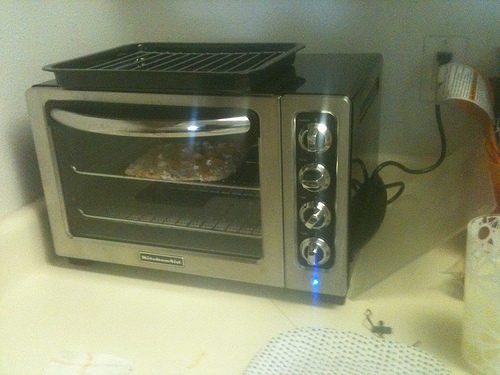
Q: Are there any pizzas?
A: Yes, there is a pizza.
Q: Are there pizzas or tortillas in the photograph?
A: Yes, there is a pizza.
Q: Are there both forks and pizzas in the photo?
A: No, there is a pizza but no forks.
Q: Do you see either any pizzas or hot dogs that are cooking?
A: Yes, the pizza is cooking.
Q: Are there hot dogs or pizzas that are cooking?
A: Yes, the pizza is cooking.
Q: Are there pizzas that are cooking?
A: Yes, there is a pizza that is cooking.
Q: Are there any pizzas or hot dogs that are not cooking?
A: No, there is a pizza but it is cooking.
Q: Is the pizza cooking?
A: Yes, the pizza is cooking.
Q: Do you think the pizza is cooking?
A: Yes, the pizza is cooking.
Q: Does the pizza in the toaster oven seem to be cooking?
A: Yes, the pizza is cooking.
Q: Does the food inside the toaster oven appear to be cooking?
A: Yes, the pizza is cooking.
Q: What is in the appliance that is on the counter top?
A: The pizza is in the toaster oven.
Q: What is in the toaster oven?
A: The pizza is in the toaster oven.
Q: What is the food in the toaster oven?
A: The food is a pizza.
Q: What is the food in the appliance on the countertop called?
A: The food is a pizza.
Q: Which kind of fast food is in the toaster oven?
A: The food is a pizza.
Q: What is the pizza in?
A: The pizza is in the toaster oven.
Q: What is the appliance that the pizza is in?
A: The appliance is a toaster oven.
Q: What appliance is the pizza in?
A: The pizza is in the toaster oven.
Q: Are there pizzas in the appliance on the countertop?
A: Yes, there is a pizza in the toaster oven.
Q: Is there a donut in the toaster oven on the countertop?
A: No, there is a pizza in the toaster oven.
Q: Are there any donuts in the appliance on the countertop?
A: No, there is a pizza in the toaster oven.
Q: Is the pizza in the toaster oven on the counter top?
A: Yes, the pizza is in the toaster oven.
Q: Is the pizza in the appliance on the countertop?
A: Yes, the pizza is in the toaster oven.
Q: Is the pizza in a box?
A: No, the pizza is in the toaster oven.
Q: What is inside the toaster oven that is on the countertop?
A: The pizza is inside the toaster oven.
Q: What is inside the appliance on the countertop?
A: The pizza is inside the toaster oven.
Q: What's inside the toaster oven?
A: The pizza is inside the toaster oven.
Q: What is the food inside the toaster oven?
A: The food is a pizza.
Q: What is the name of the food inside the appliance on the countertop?
A: The food is a pizza.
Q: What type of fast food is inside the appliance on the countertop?
A: The food is a pizza.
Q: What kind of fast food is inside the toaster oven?
A: The food is a pizza.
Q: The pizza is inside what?
A: The pizza is inside the toaster oven.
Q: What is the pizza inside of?
A: The pizza is inside the toaster oven.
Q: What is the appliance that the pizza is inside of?
A: The appliance is a toaster oven.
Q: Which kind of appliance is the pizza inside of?
A: The pizza is inside the toaster oven.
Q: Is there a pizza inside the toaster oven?
A: Yes, there is a pizza inside the toaster oven.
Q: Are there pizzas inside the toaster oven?
A: Yes, there is a pizza inside the toaster oven.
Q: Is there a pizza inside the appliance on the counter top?
A: Yes, there is a pizza inside the toaster oven.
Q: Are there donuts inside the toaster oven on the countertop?
A: No, there is a pizza inside the toaster oven.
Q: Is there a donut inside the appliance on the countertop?
A: No, there is a pizza inside the toaster oven.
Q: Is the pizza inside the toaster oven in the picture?
A: Yes, the pizza is inside the toaster oven.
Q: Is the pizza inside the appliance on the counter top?
A: Yes, the pizza is inside the toaster oven.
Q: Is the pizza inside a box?
A: No, the pizza is inside the toaster oven.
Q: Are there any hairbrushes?
A: No, there are no hairbrushes.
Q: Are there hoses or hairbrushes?
A: No, there are no hairbrushes or hoses.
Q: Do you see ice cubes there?
A: No, there are no ice cubes.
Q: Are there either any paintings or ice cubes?
A: No, there are no ice cubes or paintings.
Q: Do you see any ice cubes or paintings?
A: No, there are no ice cubes or paintings.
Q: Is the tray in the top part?
A: Yes, the tray is in the top of the image.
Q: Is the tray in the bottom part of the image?
A: No, the tray is in the top of the image.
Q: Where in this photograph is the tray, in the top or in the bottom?
A: The tray is in the top of the image.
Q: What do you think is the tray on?
A: The tray is on the toaster oven.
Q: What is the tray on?
A: The tray is on the toaster oven.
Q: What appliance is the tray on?
A: The tray is on the toaster oven.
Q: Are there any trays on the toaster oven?
A: Yes, there is a tray on the toaster oven.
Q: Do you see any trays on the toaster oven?
A: Yes, there is a tray on the toaster oven.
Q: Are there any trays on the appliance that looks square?
A: Yes, there is a tray on the toaster oven.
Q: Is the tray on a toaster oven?
A: Yes, the tray is on a toaster oven.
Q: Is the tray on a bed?
A: No, the tray is on a toaster oven.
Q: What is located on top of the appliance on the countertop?
A: The tray is on top of the toaster oven.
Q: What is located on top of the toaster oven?
A: The tray is on top of the toaster oven.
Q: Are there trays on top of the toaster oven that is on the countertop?
A: Yes, there is a tray on top of the toaster oven.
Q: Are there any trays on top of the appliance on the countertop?
A: Yes, there is a tray on top of the toaster oven.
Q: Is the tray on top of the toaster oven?
A: Yes, the tray is on top of the toaster oven.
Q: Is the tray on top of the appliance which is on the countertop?
A: Yes, the tray is on top of the toaster oven.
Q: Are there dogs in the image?
A: No, there are no dogs.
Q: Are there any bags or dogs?
A: No, there are no dogs or bags.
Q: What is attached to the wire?
A: The tag is attached to the wire.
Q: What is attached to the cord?
A: The tag is attached to the wire.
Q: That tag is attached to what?
A: The tag is attached to the cord.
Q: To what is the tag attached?
A: The tag is attached to the cord.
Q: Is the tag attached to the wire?
A: Yes, the tag is attached to the wire.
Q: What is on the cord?
A: The tag is on the cord.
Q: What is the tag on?
A: The tag is on the cord.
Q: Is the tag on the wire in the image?
A: Yes, the tag is on the wire.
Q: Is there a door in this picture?
A: Yes, there is a door.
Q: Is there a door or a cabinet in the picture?
A: Yes, there is a door.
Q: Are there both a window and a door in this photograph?
A: No, there is a door but no windows.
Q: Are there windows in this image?
A: No, there are no windows.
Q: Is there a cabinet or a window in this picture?
A: No, there are no windows or cabinets.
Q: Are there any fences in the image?
A: No, there are no fences.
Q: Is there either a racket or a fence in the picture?
A: No, there are no fences or rackets.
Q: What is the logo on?
A: The logo is on the toaster oven.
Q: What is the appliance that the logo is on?
A: The appliance is a toaster oven.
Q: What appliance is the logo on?
A: The logo is on the toaster oven.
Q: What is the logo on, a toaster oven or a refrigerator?
A: The logo is on a toaster oven.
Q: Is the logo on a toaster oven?
A: Yes, the logo is on a toaster oven.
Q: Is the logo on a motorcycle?
A: No, the logo is on a toaster oven.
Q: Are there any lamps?
A: No, there are no lamps.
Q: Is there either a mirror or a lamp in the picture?
A: No, there are no lamps or mirrors.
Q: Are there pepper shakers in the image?
A: No, there are no pepper shakers.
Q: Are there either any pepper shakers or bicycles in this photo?
A: No, there are no pepper shakers or bicycles.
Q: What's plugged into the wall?
A: The cord is plugged into the wall.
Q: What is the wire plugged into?
A: The wire is plugged into the wall.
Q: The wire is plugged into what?
A: The wire is plugged into the wall.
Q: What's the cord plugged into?
A: The wire is plugged into the wall.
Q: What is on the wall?
A: The cord is on the wall.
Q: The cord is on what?
A: The cord is on the wall.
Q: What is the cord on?
A: The cord is on the wall.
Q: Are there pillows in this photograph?
A: No, there are no pillows.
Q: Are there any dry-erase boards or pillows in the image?
A: No, there are no pillows or dry-erase boards.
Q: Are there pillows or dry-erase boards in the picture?
A: No, there are no pillows or dry-erase boards.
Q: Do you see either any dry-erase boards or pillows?
A: No, there are no pillows or dry-erase boards.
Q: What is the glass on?
A: The glass is on the countertop.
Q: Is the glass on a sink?
A: No, the glass is on the counter top.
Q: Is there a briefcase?
A: No, there are no briefcases.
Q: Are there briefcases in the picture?
A: No, there are no briefcases.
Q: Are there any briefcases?
A: No, there are no briefcases.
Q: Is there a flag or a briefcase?
A: No, there are no briefcases or flags.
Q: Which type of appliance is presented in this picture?
A: The appliance is a toaster oven.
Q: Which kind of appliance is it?
A: The appliance is a toaster oven.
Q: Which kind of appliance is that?
A: This is a toaster oven.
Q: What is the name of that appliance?
A: This is a toaster oven.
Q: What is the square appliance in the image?
A: The appliance is a toaster oven.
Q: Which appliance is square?
A: The appliance is a toaster oven.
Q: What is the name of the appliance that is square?
A: The appliance is a toaster oven.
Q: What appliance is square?
A: The appliance is a toaster oven.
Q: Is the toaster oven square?
A: Yes, the toaster oven is square.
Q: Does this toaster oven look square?
A: Yes, the toaster oven is square.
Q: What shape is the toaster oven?
A: The toaster oven is square.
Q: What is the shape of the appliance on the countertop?
A: The toaster oven is square.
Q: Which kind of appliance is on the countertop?
A: The appliance is a toaster oven.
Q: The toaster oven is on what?
A: The toaster oven is on the countertop.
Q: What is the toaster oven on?
A: The toaster oven is on the countertop.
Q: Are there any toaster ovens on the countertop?
A: Yes, there is a toaster oven on the countertop.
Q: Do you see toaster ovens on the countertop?
A: Yes, there is a toaster oven on the countertop.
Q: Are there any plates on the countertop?
A: No, there is a toaster oven on the countertop.